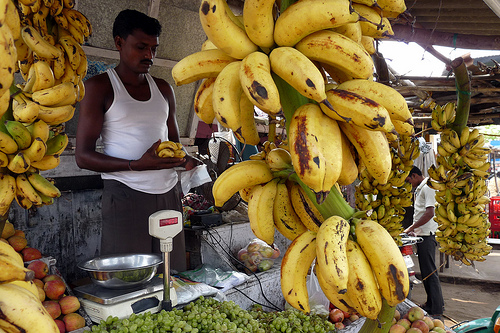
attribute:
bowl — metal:
[61, 249, 174, 300]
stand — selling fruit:
[0, 7, 459, 314]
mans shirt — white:
[85, 52, 225, 200]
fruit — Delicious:
[216, 216, 335, 297]